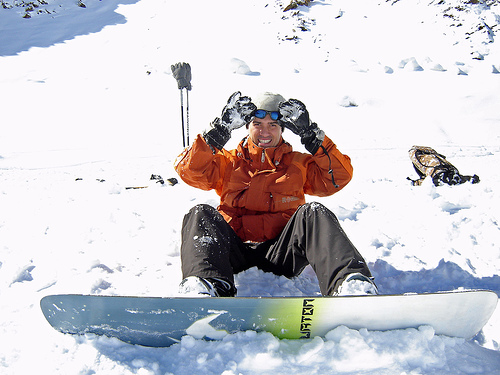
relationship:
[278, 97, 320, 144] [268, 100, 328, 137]
glove on hand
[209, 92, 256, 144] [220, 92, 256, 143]
glove on hand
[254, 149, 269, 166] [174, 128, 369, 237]
zipper on jacket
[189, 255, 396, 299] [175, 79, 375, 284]
boot on man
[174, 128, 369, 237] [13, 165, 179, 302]
jacket in snow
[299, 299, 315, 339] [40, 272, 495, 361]
words on board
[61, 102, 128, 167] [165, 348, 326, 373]
snow on ground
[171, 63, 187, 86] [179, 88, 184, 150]
glove on ski pole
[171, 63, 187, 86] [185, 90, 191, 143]
glove on ski pole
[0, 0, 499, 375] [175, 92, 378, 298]
snow beside man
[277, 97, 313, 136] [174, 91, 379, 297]
hand of man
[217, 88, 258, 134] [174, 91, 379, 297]
hand of man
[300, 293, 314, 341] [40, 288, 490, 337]
words on board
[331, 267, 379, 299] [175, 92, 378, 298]
snow boot on man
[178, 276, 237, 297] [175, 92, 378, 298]
boot on man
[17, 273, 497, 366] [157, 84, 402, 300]
board under man